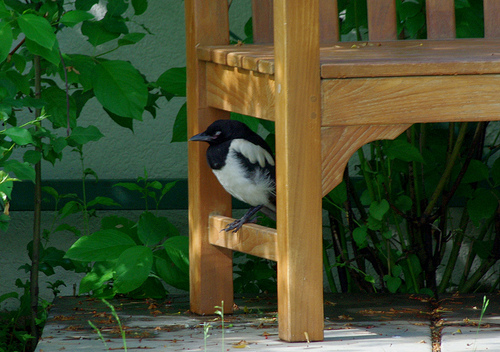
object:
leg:
[224, 204, 263, 233]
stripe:
[5, 178, 191, 210]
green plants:
[0, 3, 499, 308]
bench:
[183, 0, 497, 344]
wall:
[0, 3, 355, 330]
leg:
[219, 206, 255, 233]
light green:
[1, 0, 499, 307]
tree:
[1, 3, 152, 343]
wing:
[231, 136, 277, 167]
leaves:
[4, 0, 160, 186]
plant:
[9, 4, 162, 339]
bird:
[188, 118, 280, 234]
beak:
[187, 133, 208, 142]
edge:
[280, 287, 305, 315]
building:
[0, 0, 499, 315]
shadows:
[37, 278, 497, 343]